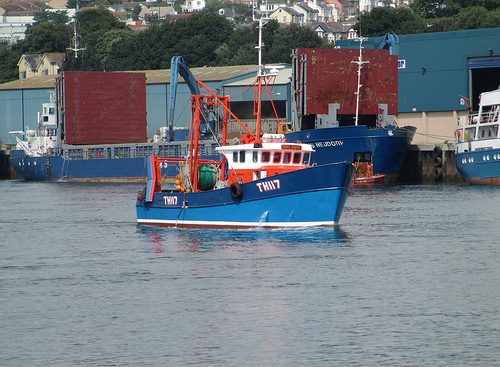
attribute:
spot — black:
[108, 313, 116, 320]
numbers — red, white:
[254, 177, 279, 192]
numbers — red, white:
[253, 173, 283, 196]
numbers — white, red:
[251, 177, 286, 197]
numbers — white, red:
[259, 177, 284, 195]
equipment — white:
[139, 88, 237, 194]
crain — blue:
[165, 52, 217, 144]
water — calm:
[4, 180, 497, 364]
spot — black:
[189, 303, 206, 312]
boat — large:
[135, 50, 360, 251]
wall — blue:
[77, 135, 167, 186]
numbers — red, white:
[251, 175, 284, 192]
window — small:
[230, 150, 240, 160]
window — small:
[236, 149, 246, 162]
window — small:
[249, 150, 258, 163]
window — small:
[259, 149, 271, 164]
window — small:
[272, 150, 282, 163]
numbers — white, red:
[160, 191, 177, 204]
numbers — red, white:
[254, 170, 281, 192]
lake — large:
[0, 116, 496, 361]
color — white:
[191, 216, 246, 225]